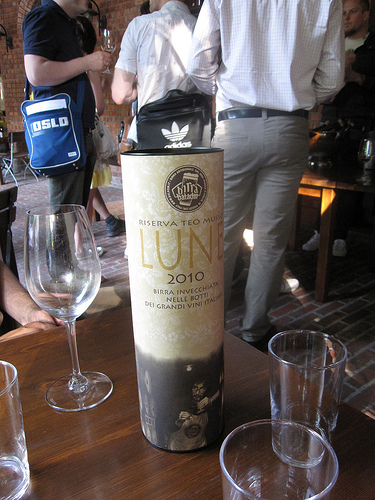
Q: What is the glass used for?
A: Wine.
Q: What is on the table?
A: A can.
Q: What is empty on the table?
A: The glass.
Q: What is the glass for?
A: Wine.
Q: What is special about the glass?
A: It's transparent.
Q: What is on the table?
A: A glass.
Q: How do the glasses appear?
A: Empty.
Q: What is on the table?
A: Wine and glasses.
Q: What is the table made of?
A: Wood.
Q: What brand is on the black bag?
A: Adidas.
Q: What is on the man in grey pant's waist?
A: Belt.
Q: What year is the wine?
A: 2010.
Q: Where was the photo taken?
A: Wine tasting store.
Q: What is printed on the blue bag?
A: Oslo.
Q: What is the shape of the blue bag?
A: Rectangle.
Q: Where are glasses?
A: On the table.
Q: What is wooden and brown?
A: Table.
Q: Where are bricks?
A: On the floor.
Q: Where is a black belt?
A: Around man's waist.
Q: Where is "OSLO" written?
A: On blue bag.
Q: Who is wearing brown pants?
A: A man.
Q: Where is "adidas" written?
A: On black bag.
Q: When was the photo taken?
A: During the daytime.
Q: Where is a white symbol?
A: On the black bag.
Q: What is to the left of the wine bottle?
A: An empty wine glass.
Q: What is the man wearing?
A: Gray pants.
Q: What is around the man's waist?
A: A black belt.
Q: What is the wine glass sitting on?
A: A wooden table.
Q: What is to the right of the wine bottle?
A: A regular glass.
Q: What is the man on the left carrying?
A: A blue and white bag.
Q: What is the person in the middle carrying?
A: A black adidas bag.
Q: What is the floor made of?
A: Red brick.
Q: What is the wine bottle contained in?
A: A round wine box.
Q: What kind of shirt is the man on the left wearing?
A: White with plaid long sleeved shirt.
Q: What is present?
A: Glasses.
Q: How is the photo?
A: Clear.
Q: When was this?
A: Daytime.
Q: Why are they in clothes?
A: To keep warm.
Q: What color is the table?
A: Brown.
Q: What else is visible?
A: Wine.